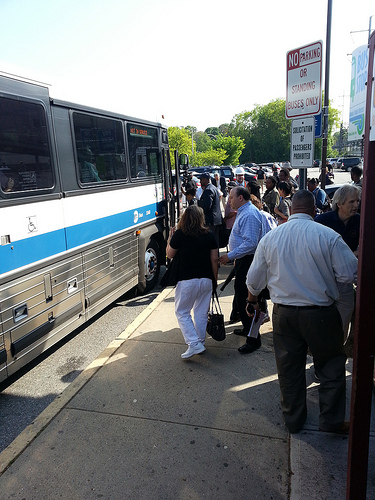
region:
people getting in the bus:
[174, 154, 272, 248]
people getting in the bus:
[134, 113, 236, 226]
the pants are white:
[168, 275, 228, 374]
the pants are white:
[164, 271, 224, 347]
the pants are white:
[166, 261, 222, 348]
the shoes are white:
[182, 342, 210, 359]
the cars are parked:
[174, 165, 279, 181]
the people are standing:
[182, 188, 344, 435]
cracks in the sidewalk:
[80, 323, 285, 495]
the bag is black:
[200, 308, 224, 349]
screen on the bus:
[125, 123, 155, 138]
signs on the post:
[284, 43, 332, 180]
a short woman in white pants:
[164, 204, 230, 365]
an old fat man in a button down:
[222, 186, 272, 348]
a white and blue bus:
[1, 71, 182, 386]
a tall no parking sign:
[281, 41, 332, 188]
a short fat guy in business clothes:
[244, 186, 354, 444]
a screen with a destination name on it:
[122, 125, 156, 141]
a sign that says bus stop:
[343, 43, 373, 149]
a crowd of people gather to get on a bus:
[183, 171, 348, 346]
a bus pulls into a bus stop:
[2, 73, 195, 375]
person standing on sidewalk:
[243, 187, 356, 438]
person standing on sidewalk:
[315, 182, 358, 371]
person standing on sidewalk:
[163, 204, 226, 361]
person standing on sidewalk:
[217, 186, 272, 354]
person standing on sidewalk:
[272, 177, 293, 224]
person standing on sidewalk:
[197, 170, 224, 246]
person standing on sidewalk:
[260, 175, 278, 218]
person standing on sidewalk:
[306, 174, 328, 220]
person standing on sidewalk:
[223, 171, 242, 195]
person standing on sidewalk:
[234, 171, 244, 188]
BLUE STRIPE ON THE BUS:
[79, 224, 102, 236]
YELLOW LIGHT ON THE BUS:
[135, 230, 137, 236]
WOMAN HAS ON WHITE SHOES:
[184, 338, 203, 355]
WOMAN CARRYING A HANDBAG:
[207, 289, 224, 336]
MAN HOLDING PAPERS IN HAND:
[248, 309, 261, 339]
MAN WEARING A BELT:
[283, 303, 312, 309]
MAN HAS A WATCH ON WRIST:
[245, 296, 261, 306]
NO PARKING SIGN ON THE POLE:
[286, 41, 321, 116]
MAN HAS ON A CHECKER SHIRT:
[234, 215, 255, 253]